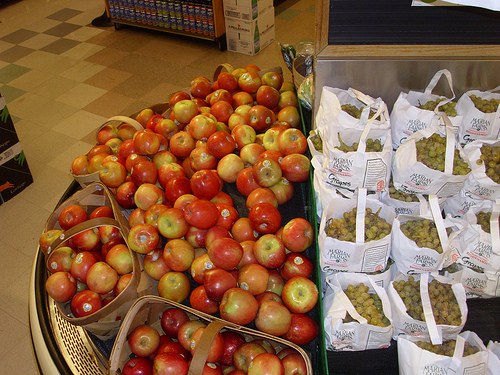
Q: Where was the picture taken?
A: At a store.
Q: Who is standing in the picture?
A: No one.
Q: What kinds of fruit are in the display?
A: Apples and grapes.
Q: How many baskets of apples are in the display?
A: Four.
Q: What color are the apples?
A: Red and yellow.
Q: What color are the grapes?
A: Green.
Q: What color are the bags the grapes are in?
A: White.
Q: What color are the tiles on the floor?
A: Various shades of brown.